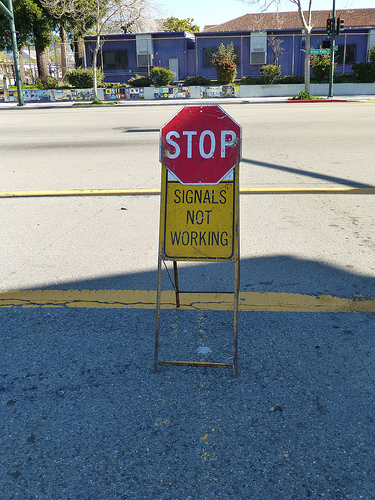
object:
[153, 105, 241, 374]
sign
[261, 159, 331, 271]
street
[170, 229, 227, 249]
letters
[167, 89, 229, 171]
sign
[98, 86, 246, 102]
wall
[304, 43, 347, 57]
street sign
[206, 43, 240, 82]
bush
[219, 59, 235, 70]
flowers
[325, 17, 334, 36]
traffic signal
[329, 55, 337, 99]
traffic pole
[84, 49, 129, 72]
window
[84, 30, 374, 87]
house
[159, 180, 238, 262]
yellow & black sign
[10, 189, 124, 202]
line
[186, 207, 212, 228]
word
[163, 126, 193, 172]
letter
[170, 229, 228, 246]
word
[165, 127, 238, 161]
stop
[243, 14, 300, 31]
roof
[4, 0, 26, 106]
tree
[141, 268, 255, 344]
stand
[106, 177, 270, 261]
sign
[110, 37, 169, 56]
fence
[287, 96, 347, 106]
curb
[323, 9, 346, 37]
light